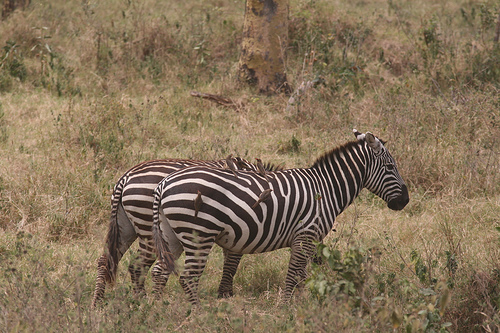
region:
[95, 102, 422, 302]
there are two zebras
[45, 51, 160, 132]
the grass is long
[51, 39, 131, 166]
the grass is green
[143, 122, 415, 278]
the zebra is stripped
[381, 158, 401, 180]
the eye is black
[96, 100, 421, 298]
the zebras are walking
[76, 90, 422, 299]
the zebras are facing right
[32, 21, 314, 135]
there's a lot of grass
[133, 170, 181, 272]
the tail is long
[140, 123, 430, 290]
the zebra is black and white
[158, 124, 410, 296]
The zebra that is fully visible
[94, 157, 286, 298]
The zebra only partially visible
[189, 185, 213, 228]
The bird on the top of the zebra's hind leg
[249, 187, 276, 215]
Bird on zebra's rib cage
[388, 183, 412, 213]
Nose of the front zebra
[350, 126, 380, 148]
Ears of the zebra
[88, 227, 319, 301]
Legs of the zebras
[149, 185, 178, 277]
Tail of the front zebra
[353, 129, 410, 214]
Head of the front zebra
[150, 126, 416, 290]
The zebra in front of the other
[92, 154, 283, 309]
The zebra behind the other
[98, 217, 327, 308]
The legs of the zebras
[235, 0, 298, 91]
Tree trunk in the background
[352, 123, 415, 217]
The head of the fully visible zebra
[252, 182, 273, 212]
Bird on the zebras rib cage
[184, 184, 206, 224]
bird on the zebras rear end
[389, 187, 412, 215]
Nose of the fully visible zebra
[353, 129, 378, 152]
Ears of the fully visible zebra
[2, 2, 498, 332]
The field the zebras are standing in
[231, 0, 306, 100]
The light brown tree bark.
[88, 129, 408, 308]
Two zebras standing together.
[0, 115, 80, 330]
Dry tan grass in the background.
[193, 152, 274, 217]
Four little birds on the zebra.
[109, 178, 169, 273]
The zebras hanging tails.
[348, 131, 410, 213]
The head of the zebra.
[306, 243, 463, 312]
Green colored weeds in the area.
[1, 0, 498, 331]
Two zebra's in a field.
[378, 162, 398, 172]
The eye of the zebra.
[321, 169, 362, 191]
The black and white stripes.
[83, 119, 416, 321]
Zebras in the medow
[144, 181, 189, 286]
Tail of zebra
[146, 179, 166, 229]
Striped part of tail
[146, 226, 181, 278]
Tuft of tail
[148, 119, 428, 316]
Zebra face right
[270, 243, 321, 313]
Front feet of zebra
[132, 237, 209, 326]
Back feet of zebra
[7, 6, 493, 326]
Field is cover with dry grass and few green plants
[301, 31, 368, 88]
Green plant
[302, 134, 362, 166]
Mane of zebra